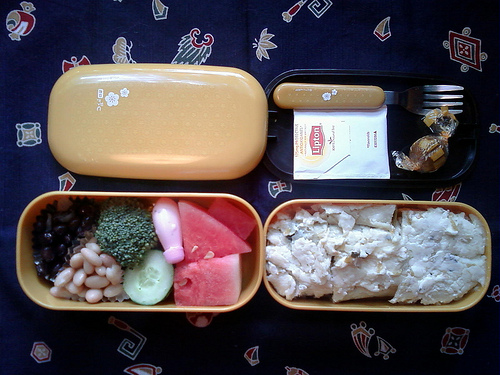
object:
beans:
[94, 264, 106, 276]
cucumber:
[122, 247, 174, 305]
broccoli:
[92, 195, 159, 272]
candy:
[390, 107, 460, 172]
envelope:
[291, 105, 392, 181]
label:
[308, 123, 326, 156]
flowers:
[119, 87, 131, 99]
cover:
[44, 61, 272, 182]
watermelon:
[172, 198, 260, 310]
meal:
[31, 192, 259, 308]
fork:
[271, 80, 468, 118]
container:
[13, 188, 268, 315]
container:
[263, 196, 495, 314]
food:
[264, 202, 491, 306]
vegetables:
[124, 226, 126, 227]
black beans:
[60, 222, 66, 226]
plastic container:
[262, 66, 492, 187]